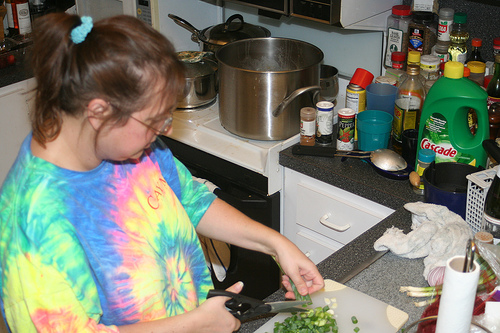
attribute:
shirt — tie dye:
[6, 155, 226, 325]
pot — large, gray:
[204, 27, 349, 148]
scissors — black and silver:
[198, 283, 354, 331]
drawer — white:
[263, 180, 392, 253]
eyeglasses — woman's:
[114, 81, 180, 141]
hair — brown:
[22, 20, 193, 138]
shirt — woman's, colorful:
[2, 138, 243, 328]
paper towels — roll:
[421, 243, 483, 325]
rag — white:
[367, 183, 477, 280]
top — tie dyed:
[1, 131, 256, 330]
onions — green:
[274, 287, 387, 331]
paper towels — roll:
[423, 248, 463, 303]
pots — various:
[152, 1, 356, 131]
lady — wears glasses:
[2, 3, 330, 331]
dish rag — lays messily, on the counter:
[369, 190, 484, 281]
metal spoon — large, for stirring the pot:
[292, 140, 410, 176]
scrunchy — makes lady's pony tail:
[68, 12, 95, 42]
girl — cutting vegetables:
[5, 10, 329, 331]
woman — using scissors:
[3, 14, 325, 327]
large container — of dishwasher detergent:
[417, 57, 484, 169]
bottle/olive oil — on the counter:
[393, 63, 420, 160]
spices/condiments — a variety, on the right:
[291, 2, 473, 185]